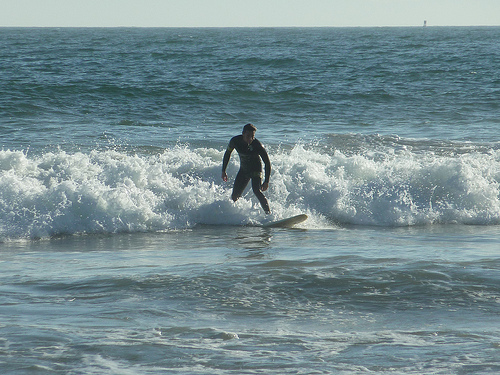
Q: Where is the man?
A: In the ocean.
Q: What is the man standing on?
A: A surfboard.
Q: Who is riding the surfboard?
A: A man.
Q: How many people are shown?
A: One.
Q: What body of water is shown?
A: An Ocean.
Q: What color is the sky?
A: Blue.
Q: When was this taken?
A: During the day.